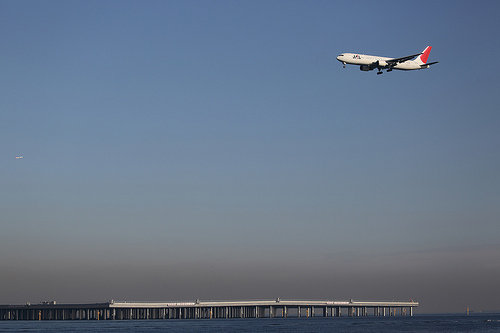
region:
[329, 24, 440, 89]
plane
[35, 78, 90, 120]
white clouds in blue sky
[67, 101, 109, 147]
white clouds in blue sky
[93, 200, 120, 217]
white clouds in blue sky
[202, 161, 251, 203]
white clouds in blue sky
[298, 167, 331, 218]
white clouds in blue sky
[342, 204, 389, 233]
white clouds in blue sky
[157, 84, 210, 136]
white clouds in blue sky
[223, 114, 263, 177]
white clouds in blue sky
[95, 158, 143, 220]
white clouds in blue sky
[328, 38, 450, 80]
plane in air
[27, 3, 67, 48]
white clouds in blue sky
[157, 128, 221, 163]
white clouds in blue sky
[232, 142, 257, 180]
white clouds in blue sky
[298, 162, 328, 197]
white clouds in blue sky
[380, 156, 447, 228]
white clouds in blue sky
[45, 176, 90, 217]
white clouds in blue sky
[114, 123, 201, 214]
white clouds in blue sky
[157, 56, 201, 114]
white clouds in blue sky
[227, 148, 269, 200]
white clouds in blue sky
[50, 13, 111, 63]
white clouds in blue sky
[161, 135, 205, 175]
white clouds in blue sky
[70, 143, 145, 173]
white clouds in blue sky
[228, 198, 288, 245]
white clouds in blue sky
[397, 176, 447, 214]
white clouds in blue sky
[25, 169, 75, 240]
white clouds in blue sky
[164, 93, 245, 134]
white clouds in blue sky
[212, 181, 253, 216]
white clouds in blue sky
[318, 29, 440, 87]
white plane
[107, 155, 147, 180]
white snow on the ground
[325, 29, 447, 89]
a plane flying through the sky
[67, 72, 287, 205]
clear blue skies over the ocean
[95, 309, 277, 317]
grey wood posts of the pier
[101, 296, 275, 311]
grey wood walls of the pier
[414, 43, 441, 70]
red tail fin of the plane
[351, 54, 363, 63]
logo on the side of the white plane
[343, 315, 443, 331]
calm blue water of the ocean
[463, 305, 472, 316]
a buoy floating in the ocean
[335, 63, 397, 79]
landing gear of the plane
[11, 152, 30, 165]
a plane flying in the distance